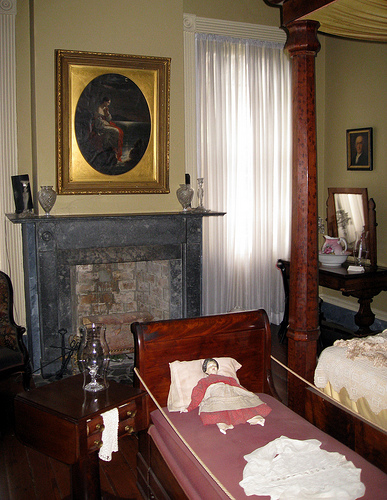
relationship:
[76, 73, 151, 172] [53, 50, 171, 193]
painting in mat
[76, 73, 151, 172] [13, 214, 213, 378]
painting above fireplace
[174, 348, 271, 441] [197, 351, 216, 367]
china doll with black hair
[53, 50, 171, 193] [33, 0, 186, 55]
mat on wall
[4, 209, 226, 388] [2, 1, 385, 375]
fireplace on wall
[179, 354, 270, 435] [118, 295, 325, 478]
china doll on bed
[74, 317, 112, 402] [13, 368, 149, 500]
vase on dresser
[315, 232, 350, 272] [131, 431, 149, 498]
vase on dresser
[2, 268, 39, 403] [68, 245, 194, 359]
chair next to fireplace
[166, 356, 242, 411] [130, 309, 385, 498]
pillow on bed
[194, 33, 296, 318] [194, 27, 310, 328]
curtains on window